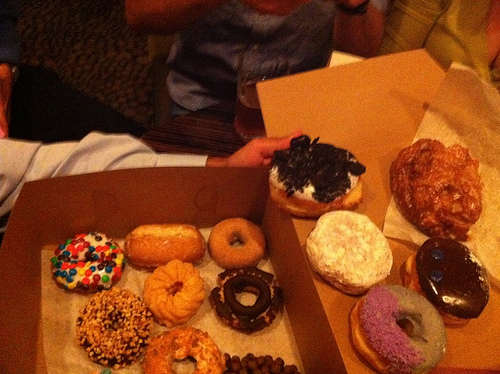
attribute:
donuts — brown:
[78, 219, 297, 373]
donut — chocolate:
[403, 236, 495, 331]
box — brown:
[5, 169, 344, 367]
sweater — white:
[3, 132, 206, 204]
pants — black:
[168, 3, 328, 111]